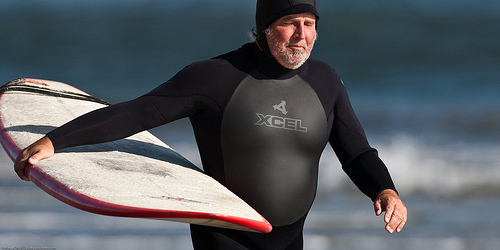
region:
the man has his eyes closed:
[243, 1, 330, 79]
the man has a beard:
[226, 6, 351, 79]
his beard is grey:
[260, 11, 355, 96]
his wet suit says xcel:
[242, 97, 309, 148]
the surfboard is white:
[9, 65, 274, 247]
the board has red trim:
[49, 188, 274, 243]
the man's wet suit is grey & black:
[194, 26, 431, 248]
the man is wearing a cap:
[248, 1, 377, 69]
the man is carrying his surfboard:
[3, 10, 424, 240]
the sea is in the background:
[391, 37, 467, 98]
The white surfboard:
[1, 65, 278, 234]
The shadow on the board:
[1, 121, 203, 173]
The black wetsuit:
[46, 0, 398, 249]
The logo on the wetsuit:
[271, 96, 294, 116]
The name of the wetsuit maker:
[251, 111, 310, 133]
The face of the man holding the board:
[263, 10, 320, 71]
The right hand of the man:
[9, 133, 57, 186]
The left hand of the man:
[367, 186, 409, 233]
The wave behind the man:
[1, 128, 498, 207]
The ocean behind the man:
[1, 1, 498, 249]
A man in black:
[200, 71, 354, 228]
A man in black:
[224, 134, 276, 225]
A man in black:
[234, 185, 254, 208]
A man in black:
[196, 76, 234, 131]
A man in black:
[240, 144, 310, 239]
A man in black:
[262, 161, 298, 242]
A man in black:
[239, 170, 265, 221]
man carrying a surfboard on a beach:
[8, 3, 480, 248]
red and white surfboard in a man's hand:
[4, 56, 268, 248]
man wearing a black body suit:
[155, 0, 426, 243]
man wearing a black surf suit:
[165, 1, 408, 236]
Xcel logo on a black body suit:
[247, 83, 315, 150]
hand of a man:
[357, 171, 426, 235]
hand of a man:
[8, 126, 71, 197]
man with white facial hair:
[253, 3, 338, 79]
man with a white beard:
[253, 8, 325, 90]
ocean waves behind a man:
[386, 21, 496, 222]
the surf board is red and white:
[211, 147, 229, 244]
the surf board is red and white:
[115, 101, 234, 200]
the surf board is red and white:
[181, 186, 243, 243]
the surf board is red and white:
[113, 152, 298, 245]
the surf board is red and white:
[146, 117, 238, 242]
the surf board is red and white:
[121, 79, 268, 231]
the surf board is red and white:
[84, 105, 214, 242]